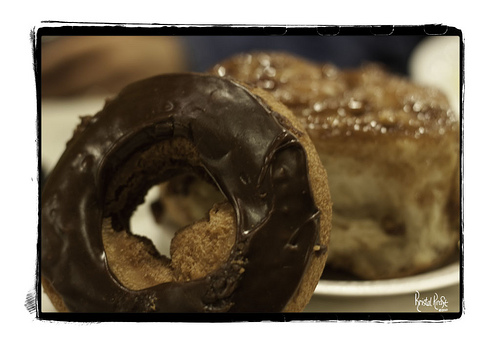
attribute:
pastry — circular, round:
[42, 71, 333, 312]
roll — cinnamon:
[61, 46, 326, 298]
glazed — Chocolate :
[117, 102, 164, 139]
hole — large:
[135, 180, 200, 243]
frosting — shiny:
[38, 73, 323, 313]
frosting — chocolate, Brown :
[42, 70, 308, 321]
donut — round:
[48, 58, 349, 330]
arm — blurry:
[41, 35, 429, 100]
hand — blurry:
[42, 35, 188, 97]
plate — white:
[311, 250, 460, 300]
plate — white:
[118, 148, 460, 303]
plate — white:
[138, 202, 462, 297]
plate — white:
[380, 263, 453, 300]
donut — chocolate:
[75, 68, 316, 344]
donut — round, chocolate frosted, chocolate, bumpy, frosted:
[39, 67, 330, 316]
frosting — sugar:
[231, 128, 297, 293]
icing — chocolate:
[32, 69, 315, 318]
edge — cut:
[331, 115, 466, 273]